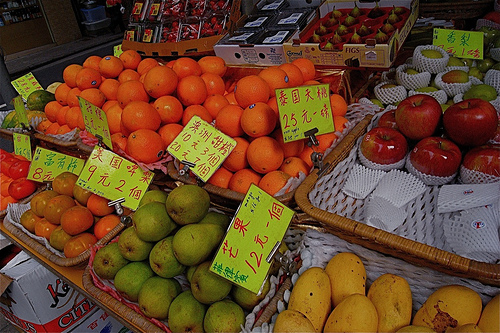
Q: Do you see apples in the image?
A: Yes, there is an apple.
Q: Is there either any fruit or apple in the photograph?
A: Yes, there is an apple.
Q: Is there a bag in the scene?
A: No, there are no bags.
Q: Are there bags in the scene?
A: No, there are no bags.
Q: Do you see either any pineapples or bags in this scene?
A: No, there are no bags or pineapples.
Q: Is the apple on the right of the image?
A: Yes, the apple is on the right of the image.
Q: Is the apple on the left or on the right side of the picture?
A: The apple is on the right of the image.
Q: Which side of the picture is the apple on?
A: The apple is on the right of the image.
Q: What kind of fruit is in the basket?
A: The fruit is an apple.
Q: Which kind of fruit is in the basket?
A: The fruit is an apple.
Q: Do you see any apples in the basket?
A: Yes, there is an apple in the basket.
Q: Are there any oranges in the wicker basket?
A: No, there is an apple in the basket.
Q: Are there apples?
A: Yes, there is an apple.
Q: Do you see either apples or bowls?
A: Yes, there is an apple.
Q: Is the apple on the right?
A: Yes, the apple is on the right of the image.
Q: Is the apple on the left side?
A: No, the apple is on the right of the image.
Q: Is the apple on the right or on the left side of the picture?
A: The apple is on the right of the image.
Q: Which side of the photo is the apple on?
A: The apple is on the right of the image.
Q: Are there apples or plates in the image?
A: Yes, there is an apple.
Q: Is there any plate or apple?
A: Yes, there is an apple.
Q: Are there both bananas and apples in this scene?
A: No, there is an apple but no bananas.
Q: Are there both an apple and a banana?
A: No, there is an apple but no bananas.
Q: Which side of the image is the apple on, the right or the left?
A: The apple is on the right of the image.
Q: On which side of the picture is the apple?
A: The apple is on the right of the image.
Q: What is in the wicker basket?
A: The apple is in the basket.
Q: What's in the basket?
A: The apple is in the basket.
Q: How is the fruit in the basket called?
A: The fruit is an apple.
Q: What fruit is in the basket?
A: The fruit is an apple.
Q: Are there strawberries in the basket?
A: No, there is an apple in the basket.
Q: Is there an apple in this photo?
A: Yes, there is an apple.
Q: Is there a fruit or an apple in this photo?
A: Yes, there is an apple.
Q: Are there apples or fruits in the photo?
A: Yes, there is an apple.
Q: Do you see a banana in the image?
A: No, there are no bananas.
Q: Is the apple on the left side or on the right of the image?
A: The apple is on the right of the image.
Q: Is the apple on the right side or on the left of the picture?
A: The apple is on the right of the image.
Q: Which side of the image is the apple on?
A: The apple is on the right of the image.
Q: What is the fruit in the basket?
A: The fruit is an apple.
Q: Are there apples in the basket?
A: Yes, there is an apple in the basket.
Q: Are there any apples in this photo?
A: Yes, there is an apple.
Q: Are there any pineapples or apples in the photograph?
A: Yes, there is an apple.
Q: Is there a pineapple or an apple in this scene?
A: Yes, there is an apple.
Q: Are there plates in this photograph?
A: No, there are no plates.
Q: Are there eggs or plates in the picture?
A: No, there are no plates or eggs.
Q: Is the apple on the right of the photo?
A: Yes, the apple is on the right of the image.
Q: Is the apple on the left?
A: No, the apple is on the right of the image.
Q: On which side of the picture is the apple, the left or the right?
A: The apple is on the right of the image.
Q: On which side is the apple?
A: The apple is on the right of the image.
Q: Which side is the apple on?
A: The apple is on the right of the image.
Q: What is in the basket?
A: The apple is in the basket.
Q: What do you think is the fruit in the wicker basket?
A: The fruit is an apple.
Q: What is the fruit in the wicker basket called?
A: The fruit is an apple.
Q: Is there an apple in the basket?
A: Yes, there is an apple in the basket.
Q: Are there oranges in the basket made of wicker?
A: No, there is an apple in the basket.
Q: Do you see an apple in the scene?
A: Yes, there is an apple.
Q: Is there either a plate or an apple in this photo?
A: Yes, there is an apple.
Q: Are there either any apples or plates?
A: Yes, there is an apple.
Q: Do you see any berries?
A: No, there are no berries.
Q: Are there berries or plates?
A: No, there are no berries or plates.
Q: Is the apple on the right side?
A: Yes, the apple is on the right of the image.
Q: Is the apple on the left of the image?
A: No, the apple is on the right of the image.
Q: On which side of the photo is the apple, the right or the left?
A: The apple is on the right of the image.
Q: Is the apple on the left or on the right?
A: The apple is on the right of the image.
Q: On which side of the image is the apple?
A: The apple is on the right of the image.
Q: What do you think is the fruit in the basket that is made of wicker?
A: The fruit is an apple.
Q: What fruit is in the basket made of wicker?
A: The fruit is an apple.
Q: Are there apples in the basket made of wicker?
A: Yes, there is an apple in the basket.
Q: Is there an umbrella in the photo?
A: No, there are no umbrellas.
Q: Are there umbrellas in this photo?
A: No, there are no umbrellas.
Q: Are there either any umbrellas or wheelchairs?
A: No, there are no umbrellas or wheelchairs.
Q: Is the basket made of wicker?
A: Yes, the basket is made of wicker.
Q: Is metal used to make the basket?
A: No, the basket is made of wicker.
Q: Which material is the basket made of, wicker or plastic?
A: The basket is made of wicker.